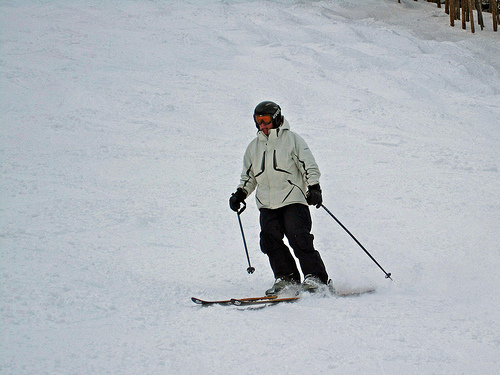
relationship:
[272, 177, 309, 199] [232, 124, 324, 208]
line on jacket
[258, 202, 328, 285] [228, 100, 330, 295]
black pants on person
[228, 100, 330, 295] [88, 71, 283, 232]
person on snow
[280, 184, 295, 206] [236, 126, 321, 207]
line on jacket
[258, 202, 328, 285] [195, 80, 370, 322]
black pants on person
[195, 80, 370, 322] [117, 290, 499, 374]
person in snow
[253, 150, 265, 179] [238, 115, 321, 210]
line on jacket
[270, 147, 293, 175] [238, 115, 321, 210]
line on jacket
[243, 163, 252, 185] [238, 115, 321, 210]
line on jacket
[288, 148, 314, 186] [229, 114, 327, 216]
line on jacket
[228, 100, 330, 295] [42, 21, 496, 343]
person on snow